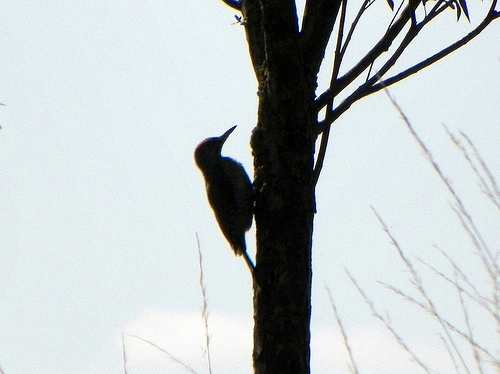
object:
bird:
[193, 124, 268, 257]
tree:
[223, 0, 499, 372]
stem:
[314, 1, 366, 186]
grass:
[119, 71, 498, 373]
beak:
[219, 124, 238, 144]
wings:
[206, 180, 249, 259]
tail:
[233, 245, 258, 271]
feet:
[251, 174, 265, 218]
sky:
[2, 2, 499, 373]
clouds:
[115, 301, 466, 373]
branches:
[225, 1, 500, 177]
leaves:
[386, 0, 471, 24]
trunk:
[253, 180, 315, 373]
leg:
[249, 180, 259, 189]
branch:
[319, 1, 464, 135]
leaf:
[387, 0, 398, 12]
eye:
[215, 144, 223, 158]